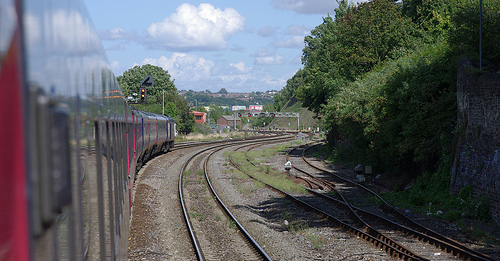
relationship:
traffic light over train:
[123, 64, 172, 170] [83, 102, 182, 152]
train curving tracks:
[110, 103, 182, 150] [144, 119, 495, 259]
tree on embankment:
[288, 0, 462, 170] [352, 145, 490, 201]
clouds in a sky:
[84, 3, 372, 98] [79, 2, 371, 114]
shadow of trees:
[235, 142, 453, 244] [301, 4, 498, 216]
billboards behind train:
[207, 97, 275, 115] [0, 4, 175, 259]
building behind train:
[218, 103, 245, 121] [1, 3, 194, 258]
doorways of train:
[119, 107, 164, 166] [22, 117, 119, 198]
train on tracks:
[69, 26, 186, 182] [173, 128, 276, 151]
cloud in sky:
[147, 3, 244, 50] [81, 3, 338, 94]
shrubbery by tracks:
[331, 34, 466, 179] [229, 117, 470, 259]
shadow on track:
[232, 197, 358, 234] [174, 132, 297, 259]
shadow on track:
[232, 197, 358, 234] [230, 135, 484, 259]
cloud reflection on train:
[33, 10, 108, 80] [0, 4, 175, 259]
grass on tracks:
[238, 140, 329, 219] [228, 127, 403, 232]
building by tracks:
[192, 106, 209, 126] [169, 136, 373, 258]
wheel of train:
[160, 141, 170, 152] [0, 4, 175, 259]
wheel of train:
[150, 144, 158, 156] [0, 4, 175, 259]